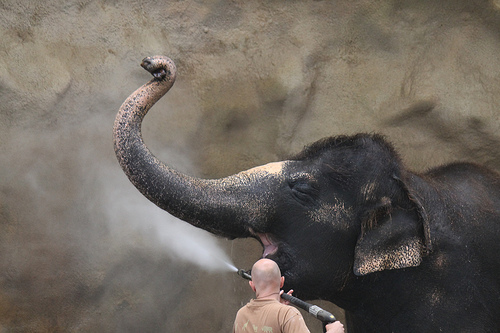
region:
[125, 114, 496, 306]
the elephant is black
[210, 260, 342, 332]
the guy is washing the elephant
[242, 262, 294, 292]
the guy is bald headed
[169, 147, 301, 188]
the trunk has a yellow patch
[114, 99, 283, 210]
the trunk is curledd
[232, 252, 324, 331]
the water spary is powerfull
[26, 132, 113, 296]
the wall is grey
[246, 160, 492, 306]
the elephant has eyes closed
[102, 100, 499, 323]
the elephnat is in the zoo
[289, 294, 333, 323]
the water gun is blak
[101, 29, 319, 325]
Elephant opening its mouth for water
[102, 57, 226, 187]
It is curving its trunk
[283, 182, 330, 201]
The elephants eye is closed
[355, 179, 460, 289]
It has discoloration on its ear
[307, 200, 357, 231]
There is discoloration on the elephants face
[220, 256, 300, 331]
The man sprays the elephant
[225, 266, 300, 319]
He uses a hose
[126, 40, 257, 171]
The end of the trunk is curled up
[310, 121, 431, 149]
The elephant has hair on its head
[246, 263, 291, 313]
The man is bald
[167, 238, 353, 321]
the man is spraying water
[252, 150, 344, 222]
the eye is closed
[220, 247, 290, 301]
the man is bald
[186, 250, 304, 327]
the man is wearing a t shirt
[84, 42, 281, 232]
the trunk is up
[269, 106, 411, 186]
the elephant has hair on its head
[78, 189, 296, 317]
the man is spraying the wall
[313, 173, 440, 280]
the ear is discolored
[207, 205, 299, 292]
the mouth is open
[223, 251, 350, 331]
man giving water to elephant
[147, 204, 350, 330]
man holding a pipe of water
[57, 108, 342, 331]
water in a mist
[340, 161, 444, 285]
ear of elephant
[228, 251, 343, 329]
person has bald head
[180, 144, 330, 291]
elephant has open mouth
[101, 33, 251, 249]
trunk of elephant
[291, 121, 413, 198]
hair on top of head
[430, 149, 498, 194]
hump of elephant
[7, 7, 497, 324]
the wall is rock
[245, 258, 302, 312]
man has no hair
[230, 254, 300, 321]
man is holding hose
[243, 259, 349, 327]
hose is black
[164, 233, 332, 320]
hose is spraying water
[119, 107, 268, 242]
elephant has black trunk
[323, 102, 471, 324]
elephant has black ears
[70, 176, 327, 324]
man is power washing elephant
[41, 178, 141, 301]
wall is light brown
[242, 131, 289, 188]
elephant has white spot on trunk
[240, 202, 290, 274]
elephant has pink mouth